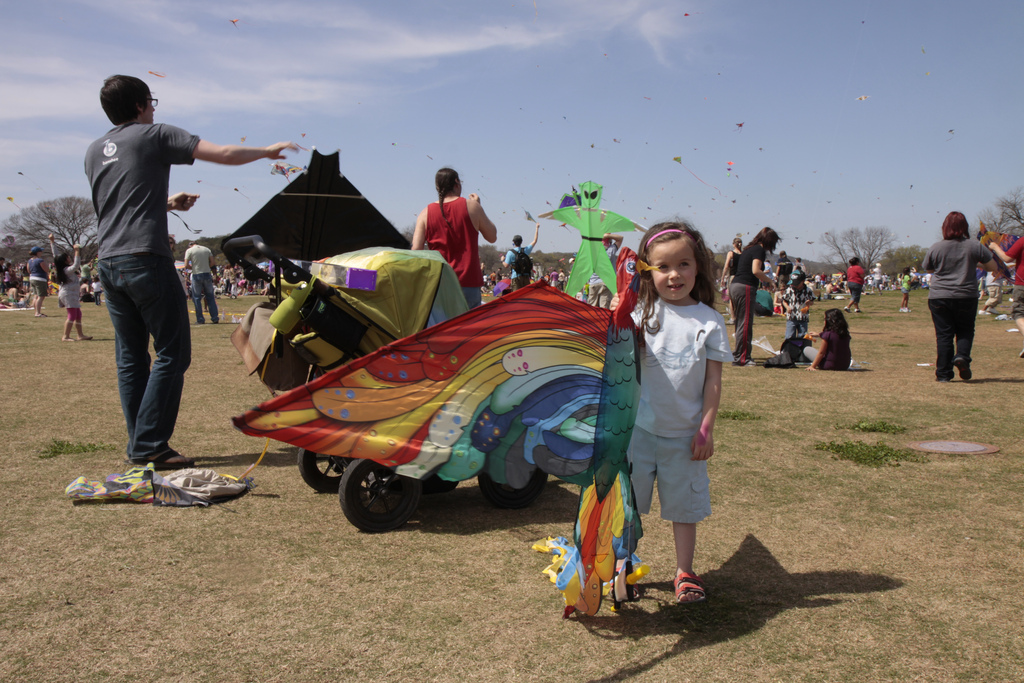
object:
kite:
[590, 143, 596, 148]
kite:
[948, 129, 956, 135]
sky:
[0, 7, 1023, 265]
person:
[498, 224, 541, 294]